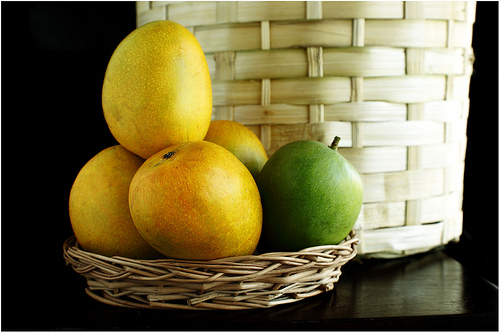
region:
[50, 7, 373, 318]
five mangos on a basket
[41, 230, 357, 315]
basket is brown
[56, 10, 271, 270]
four mangos are ripped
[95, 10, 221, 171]
a yellow mango on top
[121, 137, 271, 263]
mango has yellow and red peel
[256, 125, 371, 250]
mango is green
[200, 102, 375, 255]
a green mango next to yellow ones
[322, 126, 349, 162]
stem of mango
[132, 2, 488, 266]
a big basket behind mangos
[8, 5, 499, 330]
baskets on top a table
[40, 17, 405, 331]
The basket holds fruit.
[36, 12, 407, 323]
The basket holds four pieces of fruit.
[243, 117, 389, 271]
The fruit is green.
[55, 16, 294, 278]
The fruit is yellow.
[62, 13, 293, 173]
The fruit is balanced on the other fruit.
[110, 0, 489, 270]
A second basket is behind the fruit.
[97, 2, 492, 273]
The basket is large.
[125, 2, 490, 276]
The basket is white.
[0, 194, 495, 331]
Both baskets are on a table.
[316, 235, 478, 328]
The basket's reflection is on the table.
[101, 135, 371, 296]
plenty fruits on tray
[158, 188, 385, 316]
plenty fruits on tray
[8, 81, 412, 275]
plenty fruits on tray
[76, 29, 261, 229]
yellow fruit in basket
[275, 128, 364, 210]
green fruit next to yellow fruit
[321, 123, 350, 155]
stem of the food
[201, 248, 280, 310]
basket under the fruit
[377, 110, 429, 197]
big basket next to fruit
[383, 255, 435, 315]
table next to basket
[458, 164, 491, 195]
black background of photo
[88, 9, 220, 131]
fruit on top of other fruit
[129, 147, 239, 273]
bottom fruit on stack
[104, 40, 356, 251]
green and yellow fruit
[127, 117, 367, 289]
fruits on a tray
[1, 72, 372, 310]
fruits on a tray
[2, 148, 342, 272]
fruits on a tray